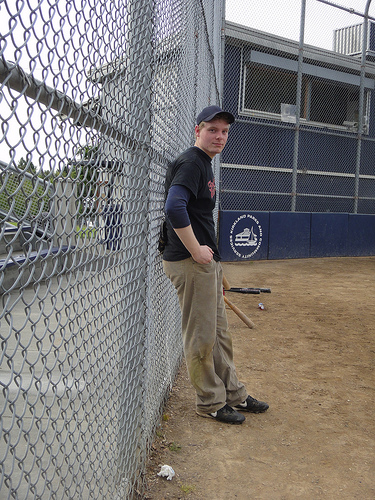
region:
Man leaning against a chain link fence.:
[124, 97, 257, 264]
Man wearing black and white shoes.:
[191, 374, 278, 431]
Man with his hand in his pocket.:
[158, 100, 249, 276]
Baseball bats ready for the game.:
[221, 269, 282, 333]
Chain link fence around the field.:
[39, 245, 111, 441]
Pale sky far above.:
[258, 22, 338, 32]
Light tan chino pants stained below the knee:
[161, 251, 251, 411]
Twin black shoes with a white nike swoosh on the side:
[193, 390, 269, 424]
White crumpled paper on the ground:
[157, 456, 176, 486]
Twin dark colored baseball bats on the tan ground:
[230, 281, 278, 298]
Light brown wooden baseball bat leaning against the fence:
[220, 284, 261, 332]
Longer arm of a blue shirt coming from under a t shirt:
[161, 165, 194, 225]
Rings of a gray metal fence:
[22, 112, 150, 465]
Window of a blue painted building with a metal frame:
[241, 48, 372, 141]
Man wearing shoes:
[192, 388, 273, 427]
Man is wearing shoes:
[192, 391, 274, 427]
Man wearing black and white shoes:
[196, 392, 268, 432]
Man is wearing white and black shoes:
[191, 384, 268, 429]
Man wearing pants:
[155, 248, 246, 411]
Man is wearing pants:
[159, 253, 251, 415]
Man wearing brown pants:
[160, 254, 252, 413]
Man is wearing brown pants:
[161, 255, 250, 411]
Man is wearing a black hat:
[191, 98, 240, 128]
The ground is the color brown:
[302, 276, 353, 488]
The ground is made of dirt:
[280, 272, 359, 495]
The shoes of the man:
[194, 381, 271, 427]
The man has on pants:
[159, 251, 251, 413]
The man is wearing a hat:
[195, 97, 239, 129]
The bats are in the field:
[220, 264, 274, 330]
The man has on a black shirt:
[156, 144, 224, 267]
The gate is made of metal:
[14, 11, 152, 473]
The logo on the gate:
[225, 213, 268, 261]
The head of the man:
[190, 102, 237, 156]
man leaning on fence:
[133, 54, 293, 459]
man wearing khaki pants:
[156, 251, 265, 421]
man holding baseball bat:
[207, 261, 277, 357]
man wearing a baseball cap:
[192, 99, 239, 133]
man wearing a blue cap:
[197, 106, 240, 123]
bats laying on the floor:
[228, 271, 285, 304]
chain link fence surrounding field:
[40, 151, 146, 240]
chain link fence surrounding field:
[16, 234, 85, 313]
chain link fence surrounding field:
[64, 352, 127, 427]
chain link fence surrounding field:
[0, 407, 62, 490]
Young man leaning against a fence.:
[161, 106, 272, 425]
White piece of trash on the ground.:
[154, 462, 178, 482]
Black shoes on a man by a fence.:
[193, 391, 271, 425]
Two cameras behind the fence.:
[342, 117, 369, 138]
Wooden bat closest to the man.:
[222, 296, 257, 330]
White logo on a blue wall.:
[223, 211, 269, 259]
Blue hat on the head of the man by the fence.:
[195, 104, 235, 124]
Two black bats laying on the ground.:
[226, 283, 277, 298]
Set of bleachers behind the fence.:
[2, 161, 88, 296]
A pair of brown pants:
[157, 251, 254, 417]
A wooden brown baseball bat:
[216, 285, 262, 332]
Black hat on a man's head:
[185, 96, 234, 157]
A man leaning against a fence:
[141, 92, 276, 429]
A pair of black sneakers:
[191, 384, 270, 429]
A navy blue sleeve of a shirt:
[155, 177, 195, 229]